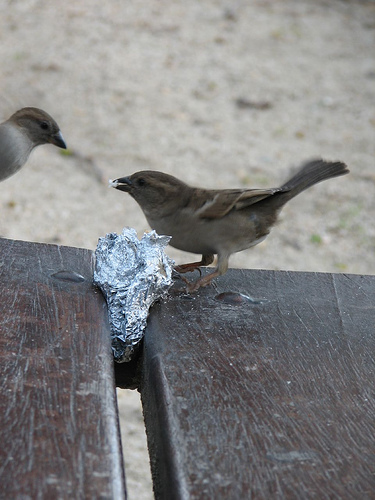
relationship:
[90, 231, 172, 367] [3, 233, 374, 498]
foil on table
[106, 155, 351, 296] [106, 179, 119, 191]
bird has foil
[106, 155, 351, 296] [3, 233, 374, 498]
bird on table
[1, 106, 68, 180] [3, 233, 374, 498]
bird on table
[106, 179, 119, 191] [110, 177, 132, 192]
foil in beak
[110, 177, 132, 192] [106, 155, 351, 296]
beak of bird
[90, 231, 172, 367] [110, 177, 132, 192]
foil in beak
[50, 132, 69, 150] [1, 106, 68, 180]
beak of bird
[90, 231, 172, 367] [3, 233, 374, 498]
foil in table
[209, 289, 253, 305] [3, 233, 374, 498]
bolt in table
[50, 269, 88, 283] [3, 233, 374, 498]
screw in table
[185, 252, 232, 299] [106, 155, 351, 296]
leg of bird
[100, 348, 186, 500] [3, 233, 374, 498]
hole in table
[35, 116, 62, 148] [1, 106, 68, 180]
face of bird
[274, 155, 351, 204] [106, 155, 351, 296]
tail of bird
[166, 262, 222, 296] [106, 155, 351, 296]
feet of bird